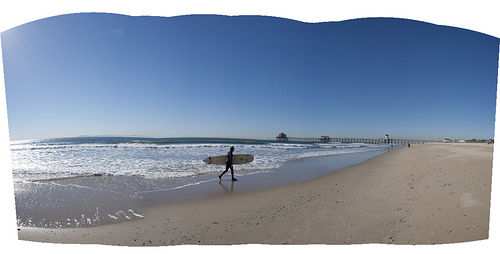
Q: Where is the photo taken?
A: At the beach.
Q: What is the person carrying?
A: A surfboard.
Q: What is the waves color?
A: White.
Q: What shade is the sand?
A: Brown.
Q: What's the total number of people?
A: 1.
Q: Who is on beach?
A: Man with a white surfboard.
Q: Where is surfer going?
A: Out of water and towards beach.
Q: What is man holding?
A: Surfboard.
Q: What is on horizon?
A: Pier leading to beach.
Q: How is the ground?
A: Brown sand.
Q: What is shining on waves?
A: The Sun.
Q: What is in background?
A: Sky and horizon.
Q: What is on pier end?
A: A small structure.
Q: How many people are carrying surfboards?
A: One.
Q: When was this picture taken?
A: Daytime.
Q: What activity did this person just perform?
A: Surfing.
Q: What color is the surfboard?
A: White.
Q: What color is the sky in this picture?
A: Blue.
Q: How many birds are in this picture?
A: Zero.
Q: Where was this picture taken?
A: The beach.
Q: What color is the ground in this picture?
A: Brown.